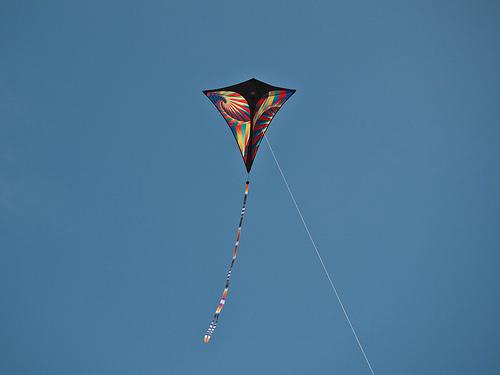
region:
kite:
[197, 68, 284, 147]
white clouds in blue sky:
[315, 175, 373, 220]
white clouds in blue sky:
[71, 149, 109, 215]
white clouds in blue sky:
[90, 164, 169, 269]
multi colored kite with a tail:
[197, 75, 298, 348]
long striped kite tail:
[200, 176, 255, 350]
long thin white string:
[261, 131, 380, 373]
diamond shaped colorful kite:
[200, 75, 301, 177]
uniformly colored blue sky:
[0, 3, 495, 374]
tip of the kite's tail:
[199, 333, 212, 343]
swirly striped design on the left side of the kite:
[198, 87, 250, 182]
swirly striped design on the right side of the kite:
[250, 75, 300, 175]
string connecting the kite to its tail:
[240, 171, 252, 186]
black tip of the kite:
[195, 73, 297, 95]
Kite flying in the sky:
[201, 76, 298, 341]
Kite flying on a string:
[194, 77, 373, 373]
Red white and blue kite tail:
[201, 173, 251, 339]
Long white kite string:
[262, 128, 377, 374]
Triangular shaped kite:
[201, 78, 298, 175]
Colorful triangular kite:
[198, 77, 297, 344]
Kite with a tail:
[198, 78, 297, 342]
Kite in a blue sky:
[197, 74, 298, 346]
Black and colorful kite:
[200, 75, 296, 342]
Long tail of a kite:
[203, 173, 253, 343]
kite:
[193, 53, 293, 166]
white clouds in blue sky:
[365, 77, 408, 122]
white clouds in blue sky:
[370, 149, 410, 176]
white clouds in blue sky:
[82, 147, 137, 232]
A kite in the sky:
[180, 76, 346, 349]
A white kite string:
[264, 132, 381, 364]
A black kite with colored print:
[201, 71, 301, 191]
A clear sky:
[61, 159, 136, 293]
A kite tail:
[192, 184, 247, 347]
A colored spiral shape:
[212, 89, 254, 123]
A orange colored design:
[222, 85, 243, 103]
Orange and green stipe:
[231, 124, 257, 157]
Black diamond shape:
[205, 67, 289, 118]